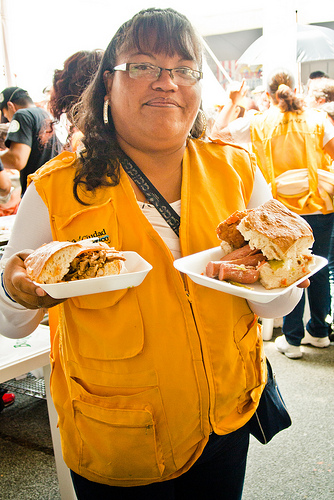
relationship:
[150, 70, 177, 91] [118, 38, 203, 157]
nose on face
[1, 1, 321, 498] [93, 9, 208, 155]
person has head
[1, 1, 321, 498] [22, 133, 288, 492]
person has shirt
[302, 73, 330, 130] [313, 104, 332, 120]
person has shirt